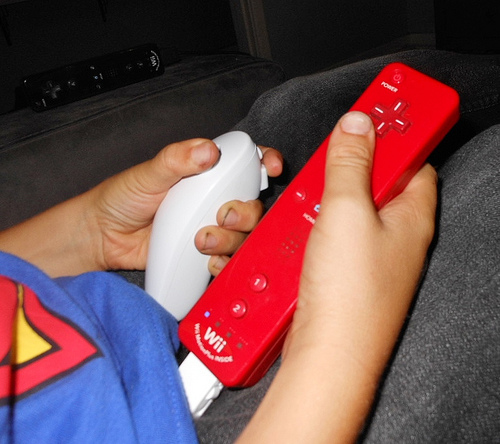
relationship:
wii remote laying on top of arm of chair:
[16, 35, 165, 115] [4, 45, 290, 185]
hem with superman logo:
[0, 247, 195, 444] [1, 278, 108, 403]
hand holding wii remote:
[107, 129, 284, 278] [144, 133, 268, 313]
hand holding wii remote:
[292, 113, 439, 389] [177, 63, 459, 391]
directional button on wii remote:
[371, 98, 410, 141] [177, 63, 459, 391]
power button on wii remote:
[390, 69, 403, 87] [177, 63, 459, 391]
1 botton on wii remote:
[245, 271, 269, 297] [177, 63, 459, 391]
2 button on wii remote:
[226, 300, 243, 318] [177, 63, 459, 391]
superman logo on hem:
[1, 278, 108, 403] [0, 247, 195, 444]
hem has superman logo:
[0, 247, 195, 444] [1, 278, 108, 403]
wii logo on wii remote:
[203, 328, 226, 353] [177, 63, 459, 391]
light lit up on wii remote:
[205, 309, 213, 318] [177, 63, 459, 391]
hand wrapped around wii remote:
[107, 129, 284, 278] [16, 35, 165, 115]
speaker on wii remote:
[277, 233, 300, 259] [177, 63, 459, 391]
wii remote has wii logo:
[177, 63, 459, 391] [203, 328, 226, 353]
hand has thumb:
[292, 113, 439, 389] [336, 101, 369, 204]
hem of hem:
[129, 281, 205, 442] [0, 247, 195, 444]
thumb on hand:
[124, 141, 218, 181] [107, 129, 284, 278]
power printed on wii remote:
[380, 79, 397, 96] [16, 35, 165, 115]